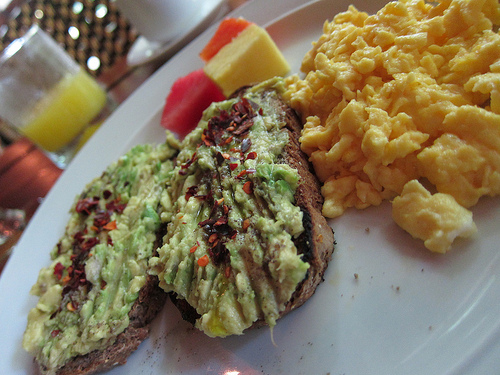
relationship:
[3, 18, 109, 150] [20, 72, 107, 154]
glass of orange juice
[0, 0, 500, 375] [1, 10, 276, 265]
plate sit on table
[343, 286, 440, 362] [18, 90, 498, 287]
plate holds food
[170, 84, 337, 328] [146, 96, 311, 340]
bread has avocado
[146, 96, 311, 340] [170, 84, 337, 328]
avocado on bread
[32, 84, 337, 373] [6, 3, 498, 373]
steak on plate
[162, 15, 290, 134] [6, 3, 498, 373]
fruit on plate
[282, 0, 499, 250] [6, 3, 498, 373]
eggs on plate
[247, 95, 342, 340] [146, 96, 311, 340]
bread with avocado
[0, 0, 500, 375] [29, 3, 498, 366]
plate of food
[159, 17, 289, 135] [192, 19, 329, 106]
fruit behind pineapple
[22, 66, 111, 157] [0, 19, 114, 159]
orange juice in glass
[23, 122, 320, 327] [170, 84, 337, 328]
avocado on top of bread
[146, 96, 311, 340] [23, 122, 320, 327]
avocado on top of avocado